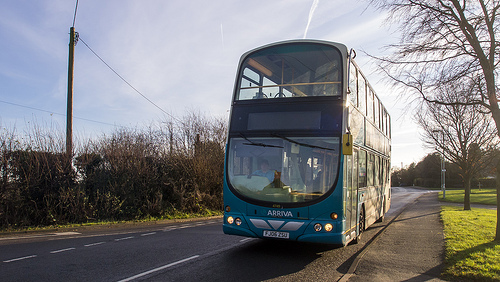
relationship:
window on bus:
[226, 136, 342, 209] [224, 41, 393, 249]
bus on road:
[224, 41, 393, 249] [1, 185, 438, 280]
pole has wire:
[66, 27, 74, 164] [71, 0, 80, 27]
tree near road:
[415, 79, 500, 209] [1, 185, 438, 280]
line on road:
[117, 255, 201, 281] [1, 185, 438, 280]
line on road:
[86, 242, 105, 248] [1, 185, 438, 280]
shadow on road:
[366, 224, 386, 229] [1, 185, 438, 280]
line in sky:
[301, 0, 317, 39] [0, 1, 499, 182]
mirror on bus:
[343, 134, 353, 156] [224, 41, 393, 249]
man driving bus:
[251, 161, 276, 182] [224, 41, 393, 249]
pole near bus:
[66, 27, 74, 164] [224, 41, 393, 249]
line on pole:
[75, 33, 197, 131] [66, 27, 74, 164]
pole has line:
[66, 27, 74, 164] [75, 33, 197, 131]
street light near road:
[433, 129, 446, 189] [1, 185, 438, 280]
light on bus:
[325, 224, 333, 231] [224, 41, 393, 249]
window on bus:
[235, 42, 344, 102] [224, 41, 393, 249]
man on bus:
[251, 161, 276, 182] [224, 41, 393, 249]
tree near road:
[357, 1, 500, 139] [1, 185, 438, 280]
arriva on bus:
[267, 210, 293, 217] [224, 41, 393, 249]